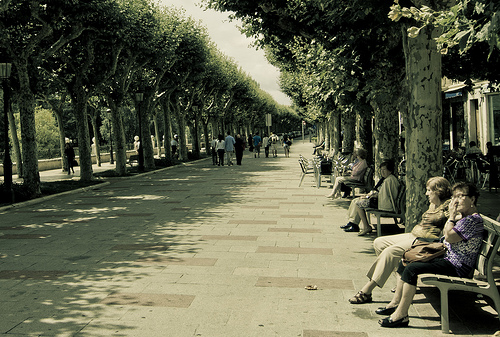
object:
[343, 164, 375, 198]
bench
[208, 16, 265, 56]
sky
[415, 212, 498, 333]
bench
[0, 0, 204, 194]
trees